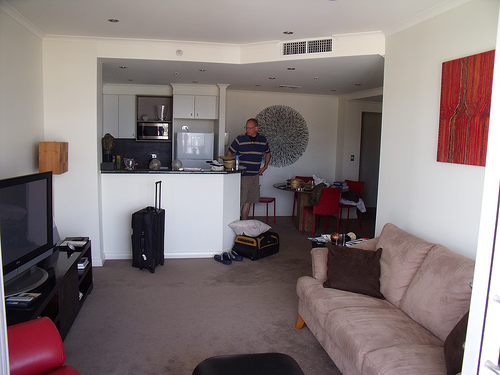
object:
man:
[227, 118, 271, 219]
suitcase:
[132, 181, 166, 273]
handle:
[152, 180, 162, 211]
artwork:
[435, 50, 492, 166]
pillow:
[324, 245, 385, 300]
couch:
[296, 223, 474, 374]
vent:
[280, 39, 335, 55]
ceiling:
[1, 1, 498, 44]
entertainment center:
[0, 171, 91, 339]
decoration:
[253, 104, 309, 168]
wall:
[229, 92, 339, 217]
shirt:
[229, 132, 271, 176]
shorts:
[240, 175, 260, 206]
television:
[1, 170, 54, 284]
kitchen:
[104, 62, 243, 173]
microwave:
[138, 122, 171, 141]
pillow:
[228, 220, 273, 237]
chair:
[303, 187, 341, 237]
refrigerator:
[174, 131, 213, 169]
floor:
[62, 216, 380, 375]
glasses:
[243, 126, 261, 131]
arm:
[8, 317, 66, 373]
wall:
[376, 16, 497, 243]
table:
[273, 181, 348, 232]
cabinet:
[196, 93, 221, 122]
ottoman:
[190, 352, 303, 375]